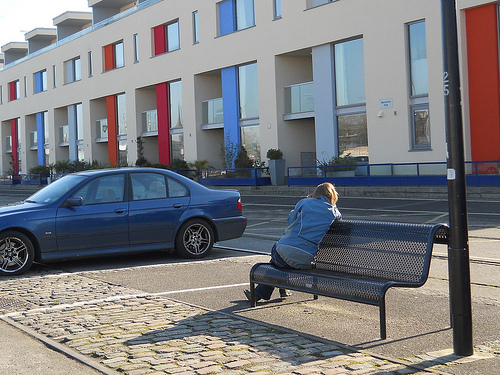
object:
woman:
[245, 181, 342, 305]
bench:
[248, 215, 453, 342]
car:
[1, 166, 247, 275]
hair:
[308, 182, 341, 208]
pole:
[439, 0, 474, 357]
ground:
[3, 268, 446, 372]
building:
[1, 2, 499, 193]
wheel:
[176, 218, 217, 259]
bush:
[232, 146, 252, 178]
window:
[14, 80, 20, 101]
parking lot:
[1, 200, 499, 375]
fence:
[285, 159, 500, 188]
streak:
[152, 83, 172, 166]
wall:
[0, 2, 498, 180]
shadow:
[122, 297, 286, 351]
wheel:
[0, 227, 38, 277]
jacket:
[276, 195, 344, 257]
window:
[41, 69, 48, 91]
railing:
[287, 158, 500, 171]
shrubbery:
[29, 164, 51, 176]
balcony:
[195, 95, 224, 131]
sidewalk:
[220, 230, 500, 287]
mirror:
[63, 195, 85, 207]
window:
[68, 170, 126, 205]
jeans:
[255, 243, 312, 302]